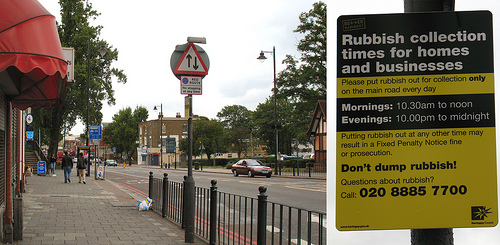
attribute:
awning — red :
[0, 1, 71, 108]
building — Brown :
[139, 114, 198, 167]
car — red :
[212, 149, 356, 193]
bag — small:
[131, 190, 159, 215]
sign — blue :
[75, 121, 107, 145]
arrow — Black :
[182, 52, 192, 69]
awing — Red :
[0, 0, 71, 110]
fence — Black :
[142, 170, 317, 244]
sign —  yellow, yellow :
[332, 9, 499, 231]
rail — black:
[132, 163, 292, 203]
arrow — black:
[192, 53, 204, 75]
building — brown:
[134, 115, 203, 166]